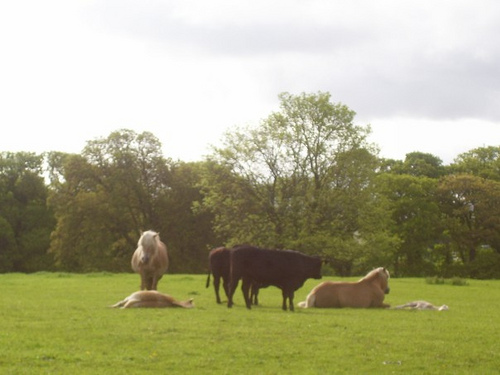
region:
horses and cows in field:
[87, 218, 369, 315]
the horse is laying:
[324, 280, 396, 300]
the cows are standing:
[200, 248, 302, 313]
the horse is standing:
[121, 227, 172, 287]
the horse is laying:
[113, 280, 205, 315]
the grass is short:
[41, 319, 131, 368]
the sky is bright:
[55, 53, 191, 142]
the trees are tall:
[237, 99, 382, 227]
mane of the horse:
[359, 260, 381, 277]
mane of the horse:
[135, 228, 155, 250]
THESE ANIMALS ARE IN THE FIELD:
[102, 213, 465, 344]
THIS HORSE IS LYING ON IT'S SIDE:
[397, 281, 449, 332]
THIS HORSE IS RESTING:
[301, 250, 397, 316]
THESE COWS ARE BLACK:
[200, 243, 330, 308]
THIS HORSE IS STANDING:
[117, 221, 178, 291]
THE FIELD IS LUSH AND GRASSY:
[0, 260, 498, 370]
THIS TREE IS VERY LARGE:
[195, 80, 405, 290]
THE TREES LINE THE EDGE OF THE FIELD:
[2, 125, 497, 295]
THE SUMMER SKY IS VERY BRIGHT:
[3, 2, 498, 193]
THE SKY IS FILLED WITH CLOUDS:
[3, 0, 495, 182]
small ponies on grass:
[101, 205, 417, 351]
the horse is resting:
[298, 254, 402, 326]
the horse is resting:
[295, 261, 437, 331]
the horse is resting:
[311, 250, 396, 327]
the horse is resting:
[303, 252, 425, 342]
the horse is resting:
[300, 270, 395, 324]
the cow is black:
[213, 234, 321, 311]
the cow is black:
[216, 225, 325, 331]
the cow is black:
[211, 228, 339, 319]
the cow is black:
[212, 235, 327, 316]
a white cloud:
[358, 39, 458, 108]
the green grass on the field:
[163, 322, 244, 370]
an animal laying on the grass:
[118, 287, 202, 316]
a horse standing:
[130, 224, 177, 286]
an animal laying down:
[406, 289, 449, 314]